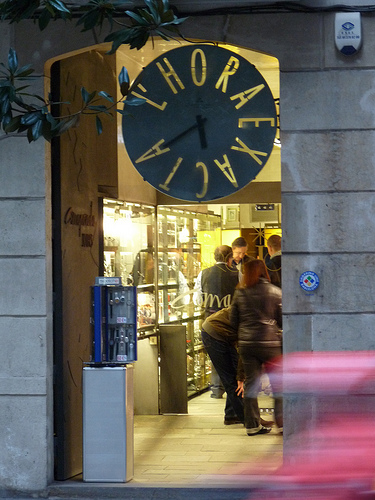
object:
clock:
[117, 41, 281, 204]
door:
[158, 323, 188, 417]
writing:
[170, 293, 232, 311]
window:
[104, 206, 155, 253]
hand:
[163, 117, 208, 149]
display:
[88, 191, 226, 393]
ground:
[200, 177, 220, 196]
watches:
[109, 299, 114, 306]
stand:
[80, 353, 139, 486]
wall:
[279, 4, 372, 485]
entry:
[43, 29, 287, 493]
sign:
[60, 198, 97, 250]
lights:
[100, 196, 158, 245]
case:
[89, 278, 139, 369]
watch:
[114, 296, 121, 305]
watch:
[120, 295, 126, 303]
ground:
[263, 130, 288, 158]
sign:
[122, 40, 280, 202]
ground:
[133, 412, 296, 481]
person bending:
[201, 285, 245, 425]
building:
[4, 2, 374, 489]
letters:
[129, 83, 168, 113]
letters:
[191, 44, 208, 88]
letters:
[214, 55, 241, 95]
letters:
[229, 83, 266, 111]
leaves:
[118, 95, 148, 109]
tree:
[0, 1, 238, 149]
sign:
[298, 266, 322, 296]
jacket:
[228, 279, 283, 350]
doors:
[115, 246, 159, 288]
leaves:
[95, 115, 104, 138]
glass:
[156, 211, 221, 382]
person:
[263, 234, 283, 290]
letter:
[155, 56, 186, 95]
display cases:
[102, 198, 220, 396]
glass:
[103, 200, 158, 335]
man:
[192, 244, 242, 399]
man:
[231, 236, 255, 283]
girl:
[225, 255, 282, 436]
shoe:
[245, 422, 274, 437]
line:
[281, 63, 374, 76]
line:
[280, 127, 375, 135]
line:
[279, 187, 374, 197]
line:
[281, 249, 375, 256]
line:
[282, 311, 375, 317]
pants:
[236, 341, 282, 431]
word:
[193, 160, 211, 202]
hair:
[243, 257, 271, 288]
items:
[105, 202, 198, 249]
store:
[37, 42, 283, 490]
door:
[41, 45, 126, 479]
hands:
[195, 109, 208, 150]